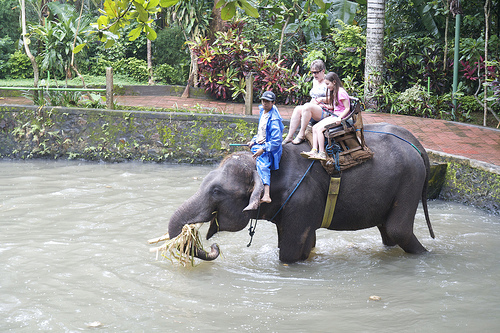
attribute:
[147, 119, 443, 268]
elephant — gray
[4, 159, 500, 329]
water — murky, murkey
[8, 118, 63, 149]
plants — watery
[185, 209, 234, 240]
mouth — open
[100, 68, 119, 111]
post — wood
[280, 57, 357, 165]
tourists — taken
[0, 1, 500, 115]
forest — dense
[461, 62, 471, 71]
leaf — colorful